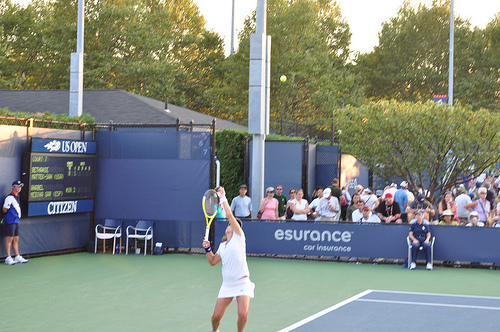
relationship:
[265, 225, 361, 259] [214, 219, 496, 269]
advertisement on partition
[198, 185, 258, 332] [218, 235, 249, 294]
woman wearing white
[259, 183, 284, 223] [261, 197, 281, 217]
woman in top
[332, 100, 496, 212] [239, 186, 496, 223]
tree among spectators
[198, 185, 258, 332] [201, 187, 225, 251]
woman with racquet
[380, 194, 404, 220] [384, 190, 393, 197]
man in hat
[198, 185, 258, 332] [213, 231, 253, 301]
woman with outfit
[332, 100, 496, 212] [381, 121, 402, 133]
tree with leaves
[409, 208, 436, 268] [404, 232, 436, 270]
referee in chair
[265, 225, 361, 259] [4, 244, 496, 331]
advertisement at tennis match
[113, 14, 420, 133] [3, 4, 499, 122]
trees in background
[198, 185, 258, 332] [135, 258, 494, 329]
woman on court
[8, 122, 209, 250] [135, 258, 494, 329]
fence beside tennis court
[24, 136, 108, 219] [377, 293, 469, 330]
scoreboard for game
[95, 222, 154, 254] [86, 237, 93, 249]
chairs in corner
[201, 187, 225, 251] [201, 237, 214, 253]
racquet in hand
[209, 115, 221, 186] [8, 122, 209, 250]
pole by fence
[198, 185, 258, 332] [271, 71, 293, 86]
woman with tennis ball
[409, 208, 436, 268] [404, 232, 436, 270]
man in chair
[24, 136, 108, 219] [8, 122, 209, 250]
scoreboard on fence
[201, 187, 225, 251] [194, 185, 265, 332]
racquet of woman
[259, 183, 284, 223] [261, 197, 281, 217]
woman in shirt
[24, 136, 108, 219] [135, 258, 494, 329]
scoreboard of court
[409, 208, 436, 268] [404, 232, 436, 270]
linesman in chair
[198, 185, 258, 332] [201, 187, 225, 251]
woman holding racquet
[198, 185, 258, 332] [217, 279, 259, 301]
woman wearing skirt